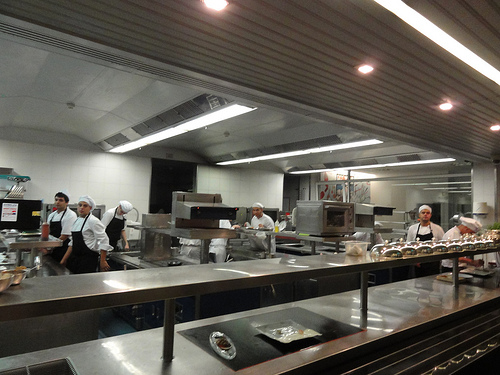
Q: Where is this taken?
A: Kitchen.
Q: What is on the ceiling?
A: Lights.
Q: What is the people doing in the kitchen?
A: Cooking.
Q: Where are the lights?
A: On top of the ceiling.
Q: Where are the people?
A: In the kitchen.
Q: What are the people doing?
A: Making food.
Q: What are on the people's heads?
A: Chef's hats.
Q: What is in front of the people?
A: A metal work station.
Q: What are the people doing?
A: Cooking.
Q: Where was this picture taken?
A: Restaurant.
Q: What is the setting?
A: Kitchen.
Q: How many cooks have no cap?
A: One.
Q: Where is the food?
A: Cooking.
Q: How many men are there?
A: Six.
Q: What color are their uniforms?
A: White.